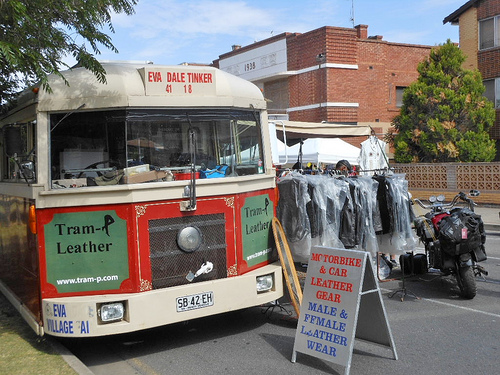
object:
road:
[0, 192, 500, 375]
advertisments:
[43, 209, 130, 293]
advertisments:
[240, 192, 276, 267]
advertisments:
[289, 245, 397, 374]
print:
[41, 303, 89, 337]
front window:
[38, 106, 268, 192]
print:
[310, 252, 362, 303]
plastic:
[281, 172, 416, 282]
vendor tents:
[257, 118, 391, 173]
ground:
[0, 186, 500, 375]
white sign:
[216, 36, 287, 81]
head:
[336, 160, 351, 174]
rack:
[273, 167, 392, 176]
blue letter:
[85, 320, 88, 334]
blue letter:
[80, 321, 85, 335]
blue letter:
[60, 304, 67, 318]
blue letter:
[68, 319, 75, 336]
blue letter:
[53, 319, 58, 333]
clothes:
[271, 160, 422, 265]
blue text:
[299, 301, 348, 357]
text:
[143, 70, 215, 93]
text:
[298, 253, 366, 360]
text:
[243, 195, 269, 236]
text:
[49, 213, 119, 288]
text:
[29, 299, 94, 337]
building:
[171, 0, 499, 206]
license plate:
[174, 290, 214, 313]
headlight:
[97, 302, 124, 323]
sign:
[147, 67, 215, 94]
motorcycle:
[410, 190, 488, 299]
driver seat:
[55, 137, 112, 180]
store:
[0, 57, 412, 341]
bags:
[274, 168, 421, 265]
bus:
[4, 58, 287, 339]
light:
[255, 273, 275, 291]